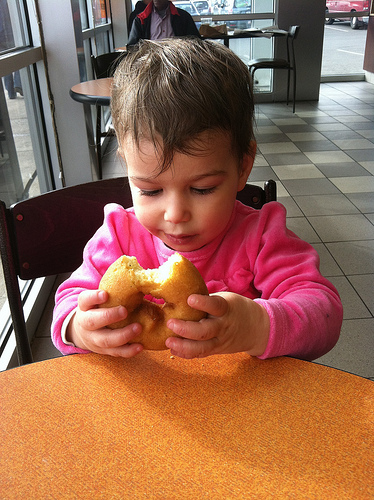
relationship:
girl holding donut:
[51, 35, 344, 362] [96, 251, 207, 352]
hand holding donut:
[165, 291, 252, 358] [96, 251, 207, 352]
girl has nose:
[51, 35, 344, 362] [163, 191, 192, 222]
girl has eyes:
[51, 35, 344, 362] [135, 180, 220, 196]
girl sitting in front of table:
[51, 35, 344, 362] [2, 344, 372, 499]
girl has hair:
[51, 35, 344, 362] [109, 32, 261, 173]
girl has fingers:
[51, 35, 344, 362] [76, 287, 229, 358]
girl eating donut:
[51, 35, 344, 362] [96, 251, 207, 352]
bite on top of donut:
[120, 252, 181, 290] [96, 251, 207, 352]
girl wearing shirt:
[51, 35, 344, 362] [49, 200, 343, 364]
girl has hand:
[51, 35, 344, 362] [164, 289, 263, 360]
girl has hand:
[51, 35, 344, 362] [72, 289, 143, 358]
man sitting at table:
[124, 0, 200, 47] [74, 72, 121, 180]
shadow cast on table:
[75, 348, 373, 499] [2, 344, 372, 499]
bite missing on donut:
[120, 252, 181, 290] [96, 251, 207, 352]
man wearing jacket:
[124, 0, 200, 47] [125, 3, 200, 42]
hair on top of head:
[109, 32, 261, 173] [109, 36, 257, 254]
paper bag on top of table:
[197, 22, 228, 40] [196, 32, 283, 50]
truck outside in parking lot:
[322, 0, 371, 29] [213, 25, 367, 78]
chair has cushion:
[246, 23, 300, 113] [247, 56, 289, 68]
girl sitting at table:
[51, 35, 344, 362] [2, 344, 372, 499]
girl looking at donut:
[51, 35, 344, 362] [96, 251, 207, 352]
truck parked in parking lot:
[322, 0, 371, 29] [213, 25, 367, 78]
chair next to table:
[246, 23, 300, 113] [196, 32, 283, 50]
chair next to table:
[87, 48, 129, 179] [74, 72, 121, 180]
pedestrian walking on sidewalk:
[1, 3, 24, 100] [1, 81, 42, 314]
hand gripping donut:
[165, 291, 252, 358] [96, 251, 207, 352]